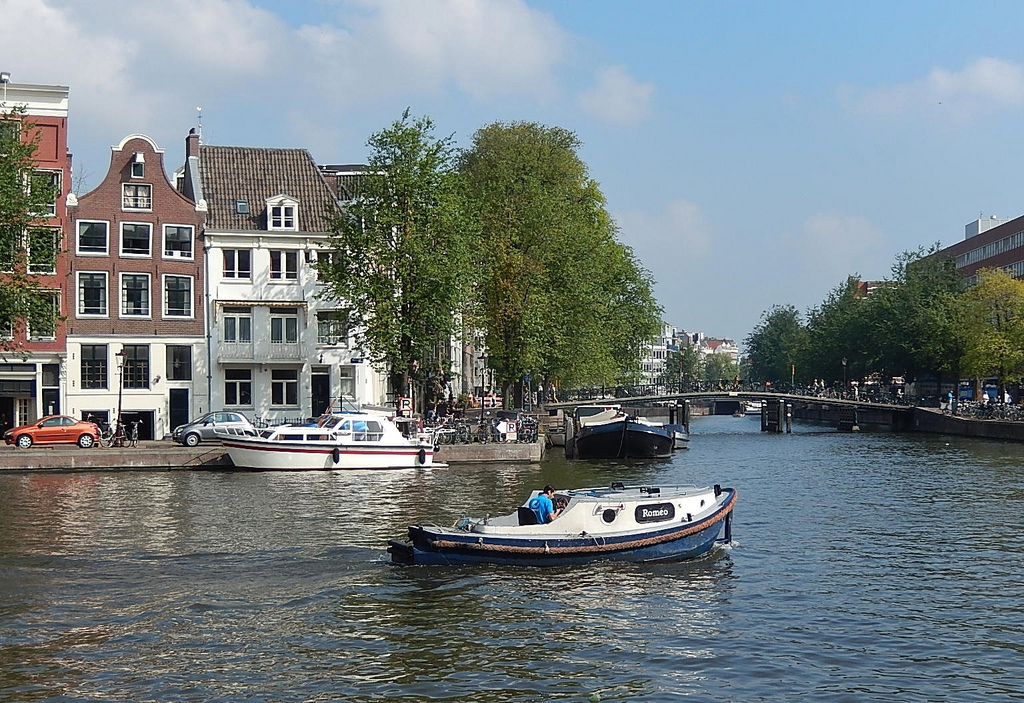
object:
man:
[529, 485, 561, 525]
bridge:
[544, 380, 914, 438]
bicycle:
[99, 417, 131, 446]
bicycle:
[131, 419, 144, 448]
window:
[600, 508, 617, 525]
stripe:
[224, 443, 435, 456]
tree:
[307, 105, 498, 426]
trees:
[451, 119, 668, 411]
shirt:
[529, 493, 556, 524]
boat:
[213, 392, 451, 469]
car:
[3, 415, 102, 449]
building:
[184, 128, 395, 427]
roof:
[180, 128, 360, 238]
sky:
[0, 0, 1022, 355]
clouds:
[0, 0, 1024, 355]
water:
[2, 414, 1024, 701]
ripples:
[0, 414, 1022, 700]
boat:
[388, 481, 739, 566]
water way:
[715, 401, 742, 416]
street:
[0, 440, 228, 452]